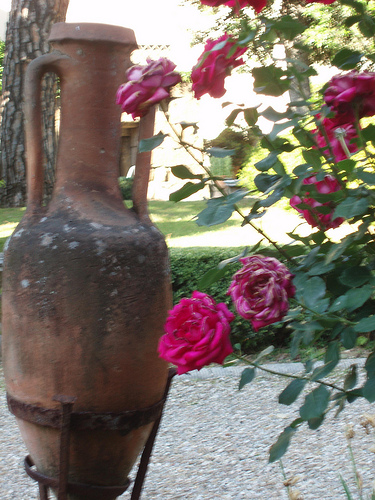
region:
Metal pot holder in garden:
[7, 365, 184, 499]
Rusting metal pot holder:
[4, 367, 179, 499]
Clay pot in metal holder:
[2, 22, 173, 498]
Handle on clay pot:
[12, 53, 60, 225]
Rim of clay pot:
[41, 17, 140, 52]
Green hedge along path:
[172, 243, 373, 360]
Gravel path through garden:
[4, 366, 371, 498]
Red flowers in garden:
[113, 0, 371, 374]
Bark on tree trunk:
[4, 3, 59, 198]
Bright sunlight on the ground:
[165, 204, 369, 249]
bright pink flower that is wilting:
[225, 252, 295, 328]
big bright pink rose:
[158, 289, 234, 371]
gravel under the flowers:
[5, 361, 374, 491]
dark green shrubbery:
[166, 246, 367, 346]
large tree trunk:
[2, 1, 67, 201]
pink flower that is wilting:
[112, 55, 183, 117]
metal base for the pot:
[5, 366, 176, 496]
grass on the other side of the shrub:
[2, 199, 370, 245]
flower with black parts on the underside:
[323, 69, 372, 118]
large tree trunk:
[285, 47, 308, 115]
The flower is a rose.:
[156, 297, 228, 361]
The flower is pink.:
[156, 298, 234, 374]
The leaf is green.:
[299, 273, 337, 319]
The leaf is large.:
[289, 271, 339, 319]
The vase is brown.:
[3, 12, 178, 498]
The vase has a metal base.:
[4, 384, 178, 498]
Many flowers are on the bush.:
[108, 12, 373, 367]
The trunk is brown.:
[7, 4, 59, 199]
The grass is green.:
[170, 240, 369, 349]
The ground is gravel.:
[169, 374, 364, 492]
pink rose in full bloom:
[171, 294, 237, 379]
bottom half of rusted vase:
[1, 384, 166, 491]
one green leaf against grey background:
[235, 367, 261, 392]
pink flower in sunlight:
[178, 27, 258, 110]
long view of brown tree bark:
[5, 87, 21, 145]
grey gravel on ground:
[193, 404, 250, 470]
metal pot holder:
[4, 391, 181, 494]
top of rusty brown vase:
[25, 14, 126, 145]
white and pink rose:
[229, 254, 302, 326]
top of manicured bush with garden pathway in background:
[175, 221, 225, 279]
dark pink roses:
[171, 283, 233, 364]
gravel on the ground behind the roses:
[179, 362, 358, 493]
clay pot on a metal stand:
[22, 127, 166, 474]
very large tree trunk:
[5, 1, 73, 217]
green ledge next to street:
[147, 237, 372, 346]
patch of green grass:
[171, 203, 314, 274]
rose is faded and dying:
[234, 248, 300, 315]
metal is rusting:
[29, 372, 245, 480]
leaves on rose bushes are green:
[295, 247, 371, 449]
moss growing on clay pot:
[37, 199, 141, 319]